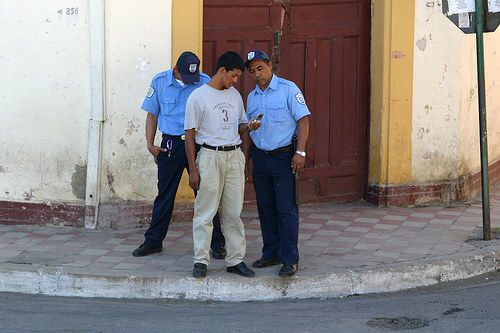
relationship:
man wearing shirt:
[129, 50, 229, 260] [242, 74, 314, 150]